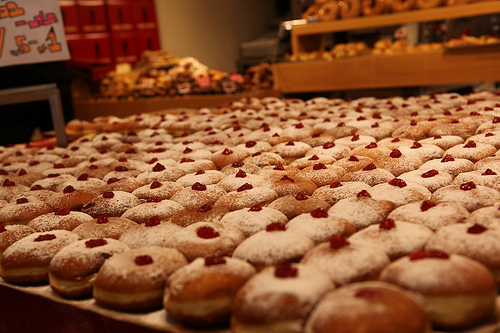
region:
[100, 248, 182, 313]
a cream puff with red fruit on top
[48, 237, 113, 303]
a cream puff with red fruit on top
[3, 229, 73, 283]
a cream puff with red fruit on top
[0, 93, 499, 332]
a table of cream puffs with red fruit on top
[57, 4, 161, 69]
red box on the wall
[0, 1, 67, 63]
a white and yellow sign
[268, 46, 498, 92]
a wood box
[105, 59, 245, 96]
snacks on a table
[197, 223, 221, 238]
small dollop of fruit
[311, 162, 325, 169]
small dollop of fruit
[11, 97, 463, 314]
doughnuts on a tray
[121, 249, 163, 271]
strawberry on the top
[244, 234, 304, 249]
white sugar on top of doughnut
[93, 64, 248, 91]
cookies piled on a plate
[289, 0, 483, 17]
doughnuts on a shelf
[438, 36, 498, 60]
pastry on a tray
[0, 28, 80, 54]
orange numbers on a sign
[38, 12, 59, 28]
pink shoe on the sign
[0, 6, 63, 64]
sign with printed items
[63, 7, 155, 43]
red colored curtain on window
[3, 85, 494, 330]
rows of pastries with jelly filling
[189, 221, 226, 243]
red jelly filling in middle of pastries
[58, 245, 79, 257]
white powdered sugar on top of pastries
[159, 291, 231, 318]
tan line in middle of pastries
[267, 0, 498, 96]
long wooden shelves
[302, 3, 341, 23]
plain cake doughnuts on wooden shelf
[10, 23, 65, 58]
numbers on white board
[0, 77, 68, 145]
metal table structure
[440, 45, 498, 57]
shadow on wooden shelf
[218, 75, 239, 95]
red and white sign in front of pastries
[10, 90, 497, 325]
dozens of raspberry jelly filled doughnuts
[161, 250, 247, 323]
a raspberry jelly filled doughnut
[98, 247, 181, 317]
raspberry jelly filled doughnuts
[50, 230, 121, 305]
raspberry jelly filled doughnuts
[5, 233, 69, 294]
raspberry jelly filled doughnuts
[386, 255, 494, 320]
raspberry jelly filled doughnuts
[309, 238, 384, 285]
raspberry jelly filled doughnuts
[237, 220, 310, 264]
raspberry jelly filled doughnuts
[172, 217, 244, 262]
raspberry jelly filled doughnuts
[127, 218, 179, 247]
raspberry jelly filled doughnuts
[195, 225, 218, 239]
Jelly on top of a pastry.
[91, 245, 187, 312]
One pastry on the table.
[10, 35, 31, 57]
.5 lettering on the sign.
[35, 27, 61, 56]
.1 lettering on the sign.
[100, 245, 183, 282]
Powdered sugar on top of the pastry.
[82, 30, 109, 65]
Red container in background.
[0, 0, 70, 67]
Sing for the pastries.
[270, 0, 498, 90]
Display stand for other pastries.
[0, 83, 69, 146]
table holding up the sign.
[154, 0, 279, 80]
Wall in the background.